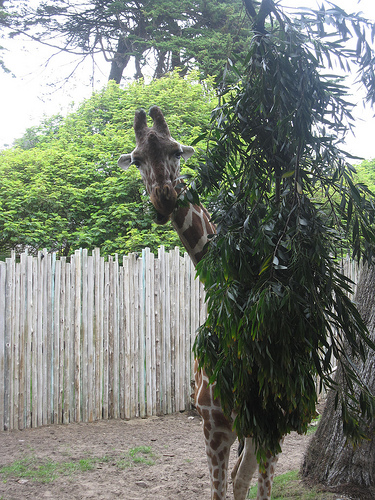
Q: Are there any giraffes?
A: Yes, there is a giraffe.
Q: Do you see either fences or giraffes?
A: Yes, there is a giraffe.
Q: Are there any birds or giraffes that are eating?
A: Yes, the giraffe is eating.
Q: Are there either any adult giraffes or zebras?
A: Yes, there is an adult giraffe.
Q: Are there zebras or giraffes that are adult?
A: Yes, the giraffe is adult.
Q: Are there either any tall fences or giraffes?
A: Yes, there is a tall giraffe.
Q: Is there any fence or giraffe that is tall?
A: Yes, the giraffe is tall.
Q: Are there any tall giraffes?
A: Yes, there is a tall giraffe.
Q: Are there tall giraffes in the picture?
A: Yes, there is a tall giraffe.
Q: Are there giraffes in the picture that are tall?
A: Yes, there is a giraffe that is tall.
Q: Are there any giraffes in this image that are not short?
A: Yes, there is a tall giraffe.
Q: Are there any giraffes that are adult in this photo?
A: Yes, there is an adult giraffe.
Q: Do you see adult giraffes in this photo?
A: Yes, there is an adult giraffe.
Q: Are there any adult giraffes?
A: Yes, there is an adult giraffe.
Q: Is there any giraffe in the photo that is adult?
A: Yes, there is a giraffe that is adult.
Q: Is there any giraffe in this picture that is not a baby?
A: Yes, there is a adult giraffe.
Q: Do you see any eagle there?
A: No, there are no eagles.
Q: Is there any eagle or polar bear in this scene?
A: No, there are no eagles or polar bears.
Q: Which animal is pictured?
A: The animal is a giraffe.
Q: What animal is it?
A: The animal is a giraffe.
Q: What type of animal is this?
A: This is a giraffe.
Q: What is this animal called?
A: This is a giraffe.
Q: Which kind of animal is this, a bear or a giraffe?
A: This is a giraffe.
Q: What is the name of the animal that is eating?
A: The animal is a giraffe.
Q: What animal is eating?
A: The animal is a giraffe.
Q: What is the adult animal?
A: The animal is a giraffe.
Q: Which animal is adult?
A: The animal is a giraffe.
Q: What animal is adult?
A: The animal is a giraffe.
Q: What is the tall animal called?
A: The animal is a giraffe.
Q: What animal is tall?
A: The animal is a giraffe.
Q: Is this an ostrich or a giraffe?
A: This is a giraffe.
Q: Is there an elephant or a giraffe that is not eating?
A: No, there is a giraffe but it is eating.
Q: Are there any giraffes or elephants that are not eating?
A: No, there is a giraffe but it is eating.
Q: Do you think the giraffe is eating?
A: Yes, the giraffe is eating.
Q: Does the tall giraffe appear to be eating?
A: Yes, the giraffe is eating.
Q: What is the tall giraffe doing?
A: The giraffe is eating.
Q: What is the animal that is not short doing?
A: The giraffe is eating.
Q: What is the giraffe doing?
A: The giraffe is eating.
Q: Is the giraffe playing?
A: No, the giraffe is eating.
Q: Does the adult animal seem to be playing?
A: No, the giraffe is eating.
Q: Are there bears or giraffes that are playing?
A: No, there is a giraffe but it is eating.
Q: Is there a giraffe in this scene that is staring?
A: No, there is a giraffe but it is eating.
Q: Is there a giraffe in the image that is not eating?
A: No, there is a giraffe but it is eating.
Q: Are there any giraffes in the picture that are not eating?
A: No, there is a giraffe but it is eating.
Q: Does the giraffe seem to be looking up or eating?
A: The giraffe is eating.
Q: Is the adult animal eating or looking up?
A: The giraffe is eating.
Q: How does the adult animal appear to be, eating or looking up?
A: The giraffe is eating.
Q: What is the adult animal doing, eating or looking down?
A: The giraffe is eating.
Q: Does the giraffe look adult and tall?
A: Yes, the giraffe is adult and tall.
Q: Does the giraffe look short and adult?
A: No, the giraffe is adult but tall.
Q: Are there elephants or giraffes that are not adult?
A: No, there is a giraffe but it is adult.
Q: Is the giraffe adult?
A: Yes, the giraffe is adult.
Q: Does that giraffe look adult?
A: Yes, the giraffe is adult.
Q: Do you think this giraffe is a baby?
A: No, the giraffe is adult.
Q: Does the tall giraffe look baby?
A: No, the giraffe is adult.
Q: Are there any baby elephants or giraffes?
A: No, there is a giraffe but it is adult.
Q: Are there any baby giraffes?
A: No, there is a giraffe but it is adult.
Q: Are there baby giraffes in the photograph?
A: No, there is a giraffe but it is adult.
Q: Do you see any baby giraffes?
A: No, there is a giraffe but it is adult.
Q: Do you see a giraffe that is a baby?
A: No, there is a giraffe but it is adult.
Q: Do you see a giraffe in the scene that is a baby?
A: No, there is a giraffe but it is adult.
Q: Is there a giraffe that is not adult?
A: No, there is a giraffe but it is adult.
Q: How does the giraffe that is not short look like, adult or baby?
A: The giraffe is adult.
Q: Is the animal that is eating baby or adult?
A: The giraffe is adult.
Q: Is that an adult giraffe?
A: Yes, that is an adult giraffe.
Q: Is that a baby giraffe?
A: No, that is an adult giraffe.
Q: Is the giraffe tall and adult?
A: Yes, the giraffe is tall and adult.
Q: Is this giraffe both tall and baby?
A: No, the giraffe is tall but adult.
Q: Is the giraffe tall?
A: Yes, the giraffe is tall.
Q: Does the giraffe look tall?
A: Yes, the giraffe is tall.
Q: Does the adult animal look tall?
A: Yes, the giraffe is tall.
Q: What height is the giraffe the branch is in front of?
A: The giraffe is tall.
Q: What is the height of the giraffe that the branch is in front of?
A: The giraffe is tall.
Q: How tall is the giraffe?
A: The giraffe is tall.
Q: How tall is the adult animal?
A: The giraffe is tall.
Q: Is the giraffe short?
A: No, the giraffe is tall.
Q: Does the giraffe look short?
A: No, the giraffe is tall.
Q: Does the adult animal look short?
A: No, the giraffe is tall.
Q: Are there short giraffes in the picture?
A: No, there is a giraffe but it is tall.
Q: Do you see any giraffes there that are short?
A: No, there is a giraffe but it is tall.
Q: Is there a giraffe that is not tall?
A: No, there is a giraffe but it is tall.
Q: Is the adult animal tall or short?
A: The giraffe is tall.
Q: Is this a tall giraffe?
A: Yes, this is a tall giraffe.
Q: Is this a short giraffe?
A: No, this is a tall giraffe.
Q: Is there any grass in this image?
A: Yes, there is grass.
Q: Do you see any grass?
A: Yes, there is grass.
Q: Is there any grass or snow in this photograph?
A: Yes, there is grass.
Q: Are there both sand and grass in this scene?
A: No, there is grass but no sand.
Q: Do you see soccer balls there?
A: No, there are no soccer balls.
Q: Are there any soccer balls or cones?
A: No, there are no soccer balls or cones.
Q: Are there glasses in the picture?
A: No, there are no glasses.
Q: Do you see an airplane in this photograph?
A: No, there are no airplanes.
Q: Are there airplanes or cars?
A: No, there are no airplanes or cars.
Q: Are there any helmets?
A: No, there are no helmets.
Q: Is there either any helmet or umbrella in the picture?
A: No, there are no helmets or umbrellas.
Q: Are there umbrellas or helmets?
A: No, there are no helmets or umbrellas.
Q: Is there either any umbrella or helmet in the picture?
A: No, there are no helmets or umbrellas.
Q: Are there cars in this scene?
A: No, there are no cars.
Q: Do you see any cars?
A: No, there are no cars.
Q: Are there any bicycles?
A: No, there are no bicycles.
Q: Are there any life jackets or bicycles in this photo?
A: No, there are no bicycles or life jackets.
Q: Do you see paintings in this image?
A: No, there are no paintings.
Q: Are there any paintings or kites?
A: No, there are no paintings or kites.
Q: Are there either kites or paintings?
A: No, there are no paintings or kites.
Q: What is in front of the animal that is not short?
A: The branch is in front of the giraffe.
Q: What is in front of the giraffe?
A: The branch is in front of the giraffe.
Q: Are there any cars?
A: No, there are no cars.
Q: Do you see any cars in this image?
A: No, there are no cars.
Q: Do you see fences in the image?
A: Yes, there is a fence.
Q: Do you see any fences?
A: Yes, there is a fence.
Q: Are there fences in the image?
A: Yes, there is a fence.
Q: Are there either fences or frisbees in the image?
A: Yes, there is a fence.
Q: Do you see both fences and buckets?
A: No, there is a fence but no buckets.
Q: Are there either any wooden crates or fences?
A: Yes, there is a wood fence.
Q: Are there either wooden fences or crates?
A: Yes, there is a wood fence.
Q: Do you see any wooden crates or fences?
A: Yes, there is a wood fence.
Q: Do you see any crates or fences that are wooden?
A: Yes, the fence is wooden.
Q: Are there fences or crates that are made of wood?
A: Yes, the fence is made of wood.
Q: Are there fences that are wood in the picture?
A: Yes, there is a wood fence.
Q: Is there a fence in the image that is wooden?
A: Yes, there is a fence that is wooden.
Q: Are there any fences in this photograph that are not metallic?
A: Yes, there is a wooden fence.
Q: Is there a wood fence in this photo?
A: Yes, there is a fence that is made of wood.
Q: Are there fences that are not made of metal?
A: Yes, there is a fence that is made of wood.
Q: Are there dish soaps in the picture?
A: No, there are no dish soaps.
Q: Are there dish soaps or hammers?
A: No, there are no dish soaps or hammers.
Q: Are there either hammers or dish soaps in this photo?
A: No, there are no dish soaps or hammers.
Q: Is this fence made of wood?
A: Yes, the fence is made of wood.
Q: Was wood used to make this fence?
A: Yes, the fence is made of wood.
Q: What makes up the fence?
A: The fence is made of wood.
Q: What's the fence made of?
A: The fence is made of wood.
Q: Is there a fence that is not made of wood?
A: No, there is a fence but it is made of wood.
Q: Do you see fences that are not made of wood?
A: No, there is a fence but it is made of wood.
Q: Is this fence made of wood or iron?
A: The fence is made of wood.